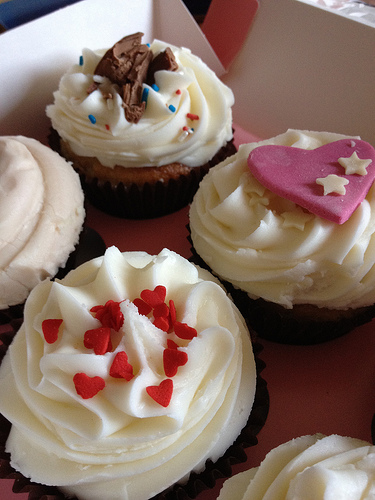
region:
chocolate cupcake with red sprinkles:
[0, 246, 259, 492]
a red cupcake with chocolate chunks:
[58, 33, 229, 211]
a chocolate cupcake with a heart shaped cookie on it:
[193, 121, 373, 348]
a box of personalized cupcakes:
[4, 37, 373, 491]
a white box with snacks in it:
[4, 1, 368, 498]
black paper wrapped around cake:
[49, 148, 235, 219]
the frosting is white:
[21, 258, 252, 474]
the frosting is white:
[9, 247, 238, 497]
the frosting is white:
[30, 249, 226, 475]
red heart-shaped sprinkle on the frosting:
[40, 298, 181, 409]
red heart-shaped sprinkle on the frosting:
[29, 276, 196, 409]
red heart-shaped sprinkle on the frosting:
[36, 278, 204, 422]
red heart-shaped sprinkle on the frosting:
[37, 285, 216, 445]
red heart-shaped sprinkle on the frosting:
[39, 287, 196, 433]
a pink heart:
[245, 136, 373, 224]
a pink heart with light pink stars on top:
[248, 137, 373, 224]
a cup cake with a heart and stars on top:
[185, 128, 374, 347]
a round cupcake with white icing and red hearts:
[2, 245, 268, 498]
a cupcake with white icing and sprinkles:
[42, 30, 235, 218]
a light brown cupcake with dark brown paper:
[186, 127, 374, 349]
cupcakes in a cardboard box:
[1, 2, 371, 497]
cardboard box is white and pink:
[1, 0, 373, 498]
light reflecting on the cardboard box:
[11, 0, 152, 66]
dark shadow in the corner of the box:
[147, 1, 160, 40]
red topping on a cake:
[142, 376, 184, 407]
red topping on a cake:
[73, 369, 112, 403]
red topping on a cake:
[110, 350, 135, 385]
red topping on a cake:
[156, 338, 187, 379]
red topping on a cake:
[170, 316, 196, 338]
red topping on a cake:
[85, 323, 118, 357]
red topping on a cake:
[43, 317, 56, 336]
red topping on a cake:
[87, 295, 124, 329]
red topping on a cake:
[137, 289, 173, 308]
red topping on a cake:
[128, 295, 152, 320]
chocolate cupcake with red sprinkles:
[4, 242, 271, 487]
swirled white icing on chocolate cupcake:
[8, 235, 261, 486]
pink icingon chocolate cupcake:
[0, 125, 83, 306]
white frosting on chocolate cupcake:
[188, 125, 373, 350]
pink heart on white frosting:
[247, 129, 373, 222]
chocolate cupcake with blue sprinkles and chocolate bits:
[44, 30, 248, 221]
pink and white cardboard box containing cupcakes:
[2, 3, 372, 490]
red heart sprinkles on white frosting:
[3, 242, 245, 482]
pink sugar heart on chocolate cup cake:
[242, 128, 374, 234]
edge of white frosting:
[219, 426, 374, 495]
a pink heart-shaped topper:
[233, 129, 374, 227]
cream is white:
[160, 399, 200, 438]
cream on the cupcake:
[194, 369, 238, 418]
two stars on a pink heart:
[248, 136, 374, 225]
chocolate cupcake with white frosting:
[186, 123, 373, 347]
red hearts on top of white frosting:
[41, 283, 196, 408]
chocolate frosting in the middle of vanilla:
[88, 30, 178, 124]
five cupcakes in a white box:
[0, 0, 372, 496]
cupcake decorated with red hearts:
[3, 241, 271, 498]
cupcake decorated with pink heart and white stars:
[188, 121, 374, 349]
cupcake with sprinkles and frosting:
[42, 31, 237, 221]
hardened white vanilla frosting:
[0, 131, 86, 314]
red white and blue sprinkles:
[78, 38, 199, 141]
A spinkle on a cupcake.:
[141, 381, 174, 405]